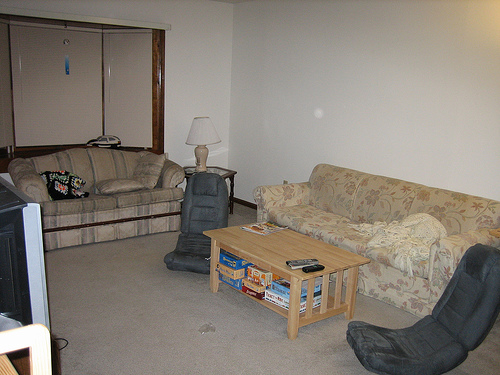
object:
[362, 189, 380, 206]
prints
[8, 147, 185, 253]
couch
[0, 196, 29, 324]
side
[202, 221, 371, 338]
coffe table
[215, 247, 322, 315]
bunch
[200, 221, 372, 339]
table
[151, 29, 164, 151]
side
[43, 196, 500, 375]
ground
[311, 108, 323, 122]
small dent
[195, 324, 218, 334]
small water spot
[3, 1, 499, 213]
white paint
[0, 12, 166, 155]
brown frame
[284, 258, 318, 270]
remotes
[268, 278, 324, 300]
games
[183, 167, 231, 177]
glass on table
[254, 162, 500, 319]
tan couch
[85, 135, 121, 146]
white car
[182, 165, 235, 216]
wood table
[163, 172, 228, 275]
right chair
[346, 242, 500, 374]
left chair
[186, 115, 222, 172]
lamp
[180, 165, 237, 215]
small table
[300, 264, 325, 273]
tv remote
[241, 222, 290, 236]
magazine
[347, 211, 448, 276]
blanket on couch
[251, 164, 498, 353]
floral couch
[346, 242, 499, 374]
black chair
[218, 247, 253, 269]
board games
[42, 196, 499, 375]
carpet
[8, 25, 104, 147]
window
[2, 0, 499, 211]
wall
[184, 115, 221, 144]
lamp shade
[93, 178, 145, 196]
pillows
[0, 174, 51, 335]
black tv